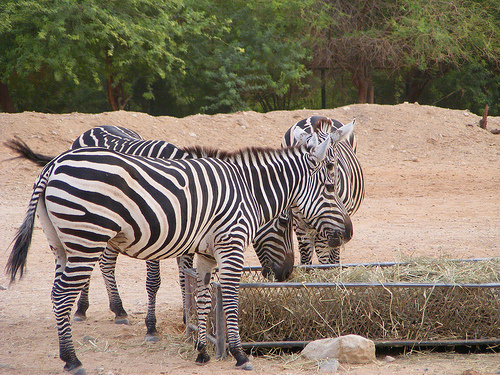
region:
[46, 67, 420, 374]
the zebras are eating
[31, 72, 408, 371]
the zebras are eating from a pen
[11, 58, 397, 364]
there are three zebras visible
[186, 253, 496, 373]
a metal pen of hay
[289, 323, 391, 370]
here is a white rock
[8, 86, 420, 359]
the zebras are in captivity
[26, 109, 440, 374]
the zebras are black and white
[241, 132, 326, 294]
this zebra is eating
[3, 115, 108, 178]
the zebra is moving its tail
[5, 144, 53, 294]
this is a zebra's tail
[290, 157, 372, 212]
the eyes of a zebra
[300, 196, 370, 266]
the mouth of a zebra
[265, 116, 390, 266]
the head of a zebra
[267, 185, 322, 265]
the jaw of a zebra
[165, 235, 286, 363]
the legs of a zebra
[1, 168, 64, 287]
the tail of a zebra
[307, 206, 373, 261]
the nose of a zebra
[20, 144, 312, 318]
the body of a zebra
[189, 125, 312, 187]
the main of a zebra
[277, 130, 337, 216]
the ear of a zebra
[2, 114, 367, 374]
Three zebras standing at feeding trough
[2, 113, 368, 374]
Group of zebras eating hay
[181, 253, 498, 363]
Wire mesh feeding trough full of hay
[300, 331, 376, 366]
Large rock on ground near feeding trough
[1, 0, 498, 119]
Green leafy trees in background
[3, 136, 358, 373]
Single zebra chewing mouthful of hay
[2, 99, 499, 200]
Bare brown dirt hill behind zebras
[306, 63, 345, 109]
Portion of fence barely visible through trees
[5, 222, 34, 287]
Bushy hair on end of zebra's tail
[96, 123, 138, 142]
Wide black stripe on zebra's back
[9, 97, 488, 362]
zebras gathered around feeding bin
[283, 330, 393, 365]
rock near the feeding bin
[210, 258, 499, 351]
feeding bin for zebras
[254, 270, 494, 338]
grass in feeding bin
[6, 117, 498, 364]
ground zebras stand on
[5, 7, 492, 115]
forest in the back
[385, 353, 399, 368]
small rock by feeding bin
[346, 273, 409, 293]
metal component of feeding bin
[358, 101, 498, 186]
angled terrain in area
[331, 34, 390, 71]
dark branches on trees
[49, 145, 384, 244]
a zebra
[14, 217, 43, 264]
the zebras tail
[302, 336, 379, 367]
a rock on the ground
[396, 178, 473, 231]
the sand is brown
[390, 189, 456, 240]
the sand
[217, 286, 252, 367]
the leg of the zebra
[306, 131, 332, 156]
the zebras ear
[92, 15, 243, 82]
the green tree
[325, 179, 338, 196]
the zebras right eye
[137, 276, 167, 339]
a zebras leg